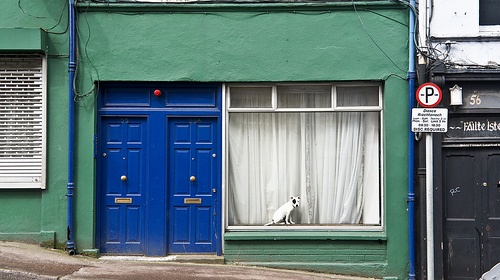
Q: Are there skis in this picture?
A: No, there are no skis.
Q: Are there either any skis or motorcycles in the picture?
A: No, there are no skis or motorcycles.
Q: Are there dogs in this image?
A: Yes, there is a dog.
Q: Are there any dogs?
A: Yes, there is a dog.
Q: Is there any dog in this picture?
A: Yes, there is a dog.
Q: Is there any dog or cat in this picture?
A: Yes, there is a dog.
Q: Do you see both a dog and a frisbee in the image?
A: No, there is a dog but no frisbees.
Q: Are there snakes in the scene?
A: No, there are no snakes.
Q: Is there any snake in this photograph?
A: No, there are no snakes.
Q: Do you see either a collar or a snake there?
A: No, there are no snakes or collars.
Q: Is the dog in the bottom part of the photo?
A: Yes, the dog is in the bottom of the image.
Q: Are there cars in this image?
A: No, there are no cars.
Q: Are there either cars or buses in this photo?
A: No, there are no cars or buses.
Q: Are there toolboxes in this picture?
A: No, there are no toolboxes.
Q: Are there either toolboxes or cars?
A: No, there are no toolboxes or cars.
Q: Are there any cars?
A: No, there are no cars.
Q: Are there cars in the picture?
A: No, there are no cars.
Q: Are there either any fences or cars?
A: No, there are no cars or fences.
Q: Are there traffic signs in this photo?
A: Yes, there is a traffic sign.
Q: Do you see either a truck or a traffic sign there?
A: Yes, there is a traffic sign.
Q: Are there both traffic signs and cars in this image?
A: No, there is a traffic sign but no cars.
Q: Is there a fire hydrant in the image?
A: No, there are no fire hydrants.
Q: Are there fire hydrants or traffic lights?
A: No, there are no fire hydrants or traffic lights.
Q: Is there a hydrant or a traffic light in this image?
A: No, there are no fire hydrants or traffic lights.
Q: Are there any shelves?
A: No, there are no shelves.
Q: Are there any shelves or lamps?
A: No, there are no shelves or lamps.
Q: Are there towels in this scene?
A: No, there are no towels.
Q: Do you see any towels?
A: No, there are no towels.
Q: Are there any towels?
A: No, there are no towels.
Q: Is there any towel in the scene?
A: No, there are no towels.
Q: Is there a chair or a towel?
A: No, there are no towels or chairs.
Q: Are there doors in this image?
A: Yes, there are doors.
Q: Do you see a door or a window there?
A: Yes, there are doors.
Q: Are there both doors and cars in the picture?
A: No, there are doors but no cars.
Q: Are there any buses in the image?
A: No, there are no buses.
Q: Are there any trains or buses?
A: No, there are no buses or trains.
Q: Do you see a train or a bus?
A: No, there are no buses or trains.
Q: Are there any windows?
A: Yes, there is a window.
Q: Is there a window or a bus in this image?
A: Yes, there is a window.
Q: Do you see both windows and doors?
A: Yes, there are both a window and a door.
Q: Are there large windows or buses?
A: Yes, there is a large window.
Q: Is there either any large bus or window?
A: Yes, there is a large window.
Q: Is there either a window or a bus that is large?
A: Yes, the window is large.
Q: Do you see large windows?
A: Yes, there is a large window.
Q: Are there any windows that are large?
A: Yes, there is a window that is large.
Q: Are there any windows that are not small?
A: Yes, there is a large window.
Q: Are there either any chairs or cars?
A: No, there are no cars or chairs.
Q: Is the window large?
A: Yes, the window is large.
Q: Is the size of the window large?
A: Yes, the window is large.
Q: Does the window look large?
A: Yes, the window is large.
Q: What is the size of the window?
A: The window is large.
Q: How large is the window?
A: The window is large.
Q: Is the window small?
A: No, the window is large.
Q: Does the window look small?
A: No, the window is large.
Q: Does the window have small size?
A: No, the window is large.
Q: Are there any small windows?
A: No, there is a window but it is large.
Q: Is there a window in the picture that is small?
A: No, there is a window but it is large.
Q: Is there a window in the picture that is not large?
A: No, there is a window but it is large.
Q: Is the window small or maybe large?
A: The window is large.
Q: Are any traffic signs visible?
A: Yes, there is a traffic sign.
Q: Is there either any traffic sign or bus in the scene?
A: Yes, there is a traffic sign.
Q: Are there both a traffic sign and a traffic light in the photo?
A: No, there is a traffic sign but no traffic lights.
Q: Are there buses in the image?
A: No, there are no buses.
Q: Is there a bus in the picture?
A: No, there are no buses.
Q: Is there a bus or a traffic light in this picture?
A: No, there are no buses or traffic lights.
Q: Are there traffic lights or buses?
A: No, there are no buses or traffic lights.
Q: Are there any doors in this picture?
A: Yes, there are doors.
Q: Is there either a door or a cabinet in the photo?
A: Yes, there are doors.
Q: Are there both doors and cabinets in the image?
A: No, there are doors but no cabinets.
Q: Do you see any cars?
A: No, there are no cars.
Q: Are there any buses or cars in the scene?
A: No, there are no cars or buses.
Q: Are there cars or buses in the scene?
A: No, there are no cars or buses.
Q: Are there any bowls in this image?
A: No, there are no bowls.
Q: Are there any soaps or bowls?
A: No, there are no bowls or soaps.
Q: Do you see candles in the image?
A: No, there are no candles.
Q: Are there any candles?
A: No, there are no candles.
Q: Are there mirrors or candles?
A: No, there are no candles or mirrors.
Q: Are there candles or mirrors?
A: No, there are no candles or mirrors.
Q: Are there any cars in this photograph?
A: No, there are no cars.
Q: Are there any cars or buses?
A: No, there are no cars or buses.